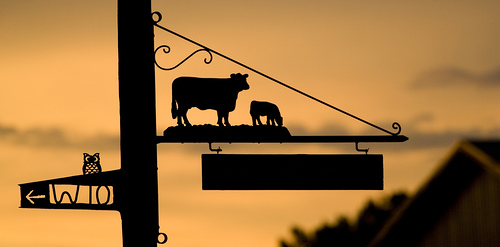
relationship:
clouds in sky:
[405, 65, 499, 96] [2, 3, 496, 246]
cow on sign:
[248, 99, 281, 123] [19, 0, 408, 246]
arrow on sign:
[26, 188, 44, 204] [19, 0, 408, 246]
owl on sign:
[81, 152, 103, 175] [19, 0, 408, 246]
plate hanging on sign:
[201, 142, 384, 192] [19, 0, 408, 246]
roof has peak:
[371, 139, 500, 242] [418, 122, 499, 178]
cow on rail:
[170, 73, 250, 126] [158, 122, 410, 143]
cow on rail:
[248, 99, 281, 123] [158, 122, 410, 143]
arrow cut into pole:
[26, 188, 44, 204] [19, 0, 408, 246]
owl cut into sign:
[53, 183, 111, 203] [19, 0, 408, 246]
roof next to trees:
[371, 139, 500, 242] [277, 193, 402, 244]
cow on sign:
[170, 73, 250, 126] [19, 0, 408, 246]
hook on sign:
[157, 230, 169, 245] [19, 0, 408, 246]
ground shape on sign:
[166, 124, 288, 136] [19, 0, 408, 246]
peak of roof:
[418, 122, 499, 178] [371, 139, 500, 242]